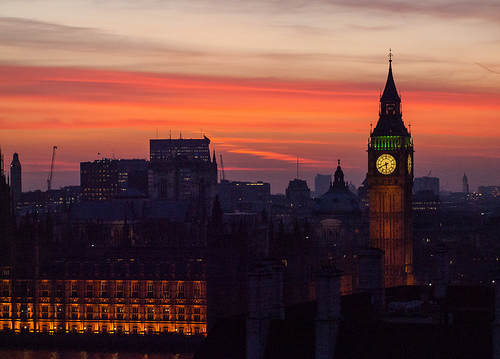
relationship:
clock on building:
[374, 153, 397, 174] [359, 45, 419, 299]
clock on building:
[402, 151, 414, 176] [359, 45, 419, 299]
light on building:
[140, 324, 151, 333] [2, 188, 250, 357]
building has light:
[2, 184, 302, 356] [161, 306, 171, 318]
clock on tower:
[369, 149, 402, 177] [345, 37, 433, 307]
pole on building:
[290, 152, 302, 174] [284, 172, 310, 202]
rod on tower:
[379, 47, 399, 79] [354, 40, 426, 294]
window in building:
[2, 275, 12, 295] [2, 240, 265, 356]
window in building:
[113, 279, 129, 298] [2, 240, 265, 356]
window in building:
[100, 290, 176, 357] [0, 249, 309, 357]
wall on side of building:
[0, 194, 287, 353] [2, 142, 275, 356]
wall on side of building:
[0, 254, 226, 354] [2, 159, 328, 355]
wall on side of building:
[0, 254, 226, 354] [2, 201, 267, 355]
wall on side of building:
[0, 254, 226, 354] [2, 126, 385, 353]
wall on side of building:
[0, 254, 226, 354] [0, 136, 311, 352]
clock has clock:
[374, 153, 397, 174] [374, 153, 397, 174]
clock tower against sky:
[352, 33, 420, 324] [5, 14, 497, 223]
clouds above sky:
[27, 0, 486, 92] [20, 3, 480, 181]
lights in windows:
[67, 138, 140, 215] [64, 138, 198, 203]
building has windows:
[57, 149, 187, 211] [64, 138, 198, 203]